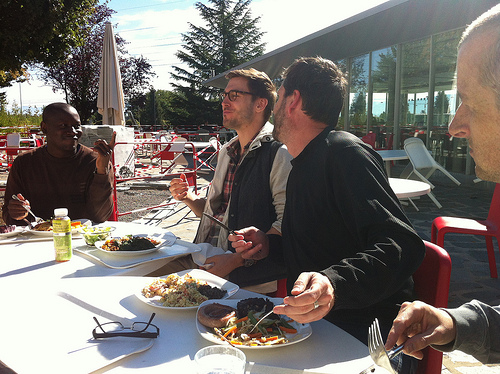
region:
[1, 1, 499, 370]
Men sitting around a table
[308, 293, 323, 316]
Silver ring around a finger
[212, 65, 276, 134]
Man is wearing eyeglasses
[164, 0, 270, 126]
A tall pine tree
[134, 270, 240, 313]
A plate full of food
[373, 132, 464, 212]
White chair against a table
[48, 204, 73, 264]
Bottle with a white cap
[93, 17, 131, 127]
A closed white umbrella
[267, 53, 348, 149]
Brown hair on man's head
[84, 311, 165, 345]
A pair of eyeglasses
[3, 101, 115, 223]
a man wearing a brown shirt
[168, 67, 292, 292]
a man wearing a black and white jacket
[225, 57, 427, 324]
a man in a black shirt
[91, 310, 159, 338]
a pair of glasses on the table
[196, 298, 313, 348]
a white plate full of food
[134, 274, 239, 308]
a white plate full of food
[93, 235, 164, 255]
a white plate full of food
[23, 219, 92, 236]
a white plate full of food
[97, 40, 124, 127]
a folded up patio table umbrella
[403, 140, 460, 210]
a white chair leaning on a table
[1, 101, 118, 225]
a man in a brown shirt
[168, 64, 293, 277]
a man in a flanel shirt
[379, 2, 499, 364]
a man in a grey shirt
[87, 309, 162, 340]
a pair of glasses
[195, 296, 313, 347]
a white ceramic plate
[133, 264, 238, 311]
a white ceramic plate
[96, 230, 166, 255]
a white ceramic plate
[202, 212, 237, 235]
a silver knife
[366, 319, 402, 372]
a silver fork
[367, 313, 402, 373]
part of a silver fork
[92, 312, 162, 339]
a pair of eyeglasses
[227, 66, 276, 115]
short brown hair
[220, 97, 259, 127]
a man's beard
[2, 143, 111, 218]
a man's brown shirt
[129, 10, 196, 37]
part of a white cloud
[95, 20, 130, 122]
part of a beige umbrella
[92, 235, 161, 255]
a white plate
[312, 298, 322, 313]
a silver ring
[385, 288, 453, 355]
the hand of a man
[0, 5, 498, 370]
Four men eating at an outdoor table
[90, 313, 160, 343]
Pair of glasses on the table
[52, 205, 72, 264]
Plastic beverage bottle on the table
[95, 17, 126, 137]
Closed umbrella on the patio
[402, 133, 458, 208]
Chair leaning against table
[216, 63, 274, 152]
Man wearing glasses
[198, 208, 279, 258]
Knife in man's right hand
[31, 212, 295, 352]
Plates of food on the table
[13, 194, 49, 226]
Fork in man's right hand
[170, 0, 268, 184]
Tree behind the building